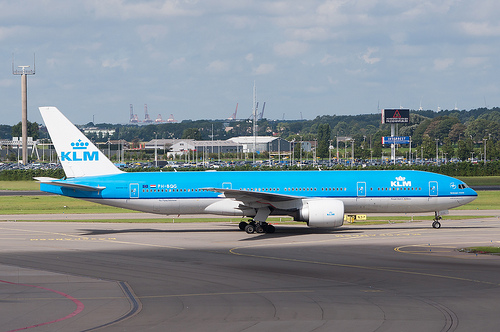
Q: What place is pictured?
A: It is a runway.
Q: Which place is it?
A: It is a runway.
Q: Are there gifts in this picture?
A: No, there are no gifts.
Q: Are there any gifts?
A: No, there are no gifts.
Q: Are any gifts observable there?
A: No, there are no gifts.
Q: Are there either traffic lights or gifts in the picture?
A: No, there are no gifts or traffic lights.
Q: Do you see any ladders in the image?
A: No, there are no ladders.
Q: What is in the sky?
A: The clouds are in the sky.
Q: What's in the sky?
A: The clouds are in the sky.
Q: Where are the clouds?
A: The clouds are in the sky.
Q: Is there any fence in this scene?
A: No, there are no fences.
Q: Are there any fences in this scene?
A: No, there are no fences.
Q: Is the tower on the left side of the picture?
A: Yes, the tower is on the left of the image.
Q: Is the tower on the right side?
A: No, the tower is on the left of the image.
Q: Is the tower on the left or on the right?
A: The tower is on the left of the image.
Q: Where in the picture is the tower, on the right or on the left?
A: The tower is on the left of the image.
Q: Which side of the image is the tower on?
A: The tower is on the left of the image.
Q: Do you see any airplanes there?
A: Yes, there is an airplane.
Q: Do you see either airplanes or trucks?
A: Yes, there is an airplane.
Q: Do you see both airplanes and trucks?
A: No, there is an airplane but no trucks.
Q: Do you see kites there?
A: No, there are no kites.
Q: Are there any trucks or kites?
A: No, there are no kites or trucks.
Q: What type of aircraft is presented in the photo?
A: The aircraft is an airplane.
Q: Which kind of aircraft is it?
A: The aircraft is an airplane.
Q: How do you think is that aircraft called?
A: This is an airplane.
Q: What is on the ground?
A: The airplane is on the ground.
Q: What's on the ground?
A: The airplane is on the ground.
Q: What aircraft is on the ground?
A: The aircraft is an airplane.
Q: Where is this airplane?
A: The airplane is on the ground.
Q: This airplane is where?
A: The airplane is on the ground.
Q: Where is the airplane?
A: The airplane is on the ground.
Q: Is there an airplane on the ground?
A: Yes, there is an airplane on the ground.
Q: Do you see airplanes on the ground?
A: Yes, there is an airplane on the ground.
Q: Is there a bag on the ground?
A: No, there is an airplane on the ground.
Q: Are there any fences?
A: No, there are no fences.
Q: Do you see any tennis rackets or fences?
A: No, there are no fences or tennis rackets.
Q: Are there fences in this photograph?
A: No, there are no fences.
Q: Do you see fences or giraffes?
A: No, there are no fences or giraffes.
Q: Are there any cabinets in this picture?
A: No, there are no cabinets.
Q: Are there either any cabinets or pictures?
A: No, there are no cabinets or pictures.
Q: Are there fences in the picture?
A: No, there are no fences.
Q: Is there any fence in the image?
A: No, there are no fences.